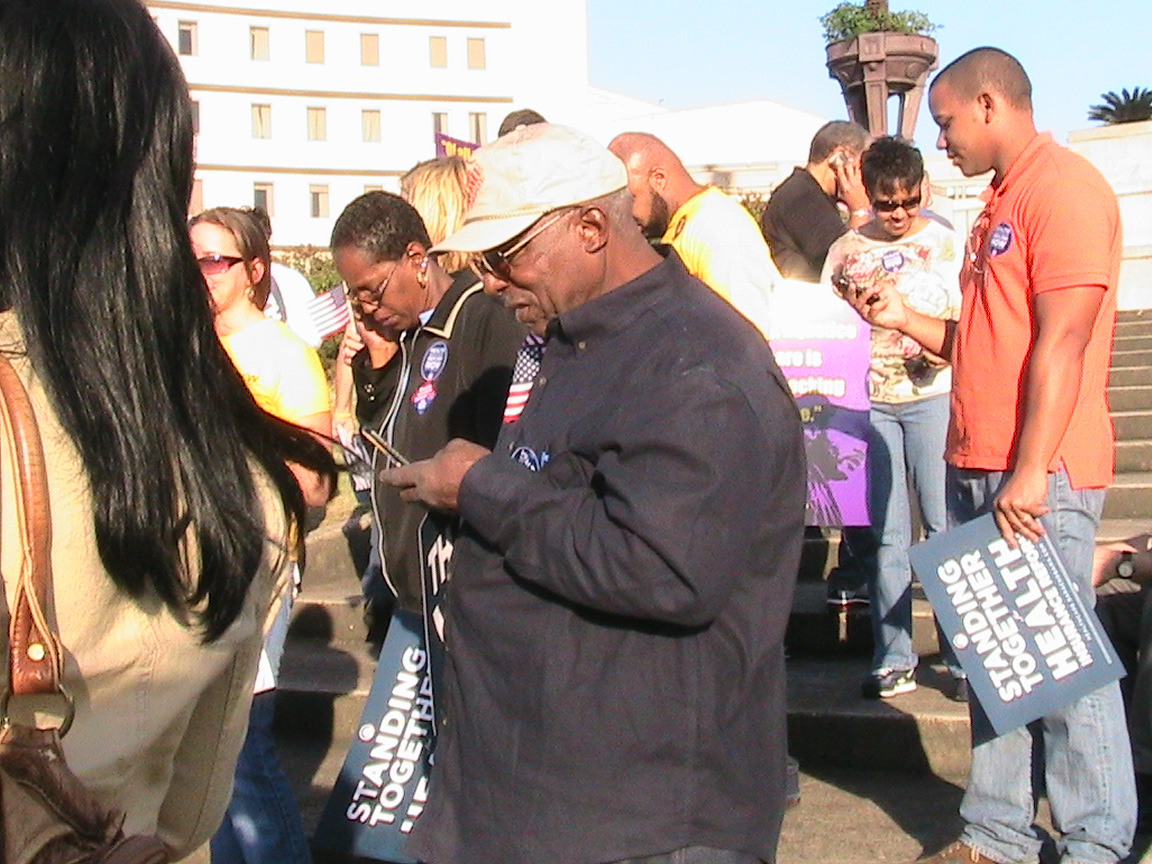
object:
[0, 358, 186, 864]
bag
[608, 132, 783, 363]
man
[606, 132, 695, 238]
head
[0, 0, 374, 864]
person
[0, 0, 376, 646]
hair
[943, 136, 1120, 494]
shirt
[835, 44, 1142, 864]
man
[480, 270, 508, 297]
nose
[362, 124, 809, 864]
person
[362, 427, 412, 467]
cell phone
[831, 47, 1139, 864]
man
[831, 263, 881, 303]
cell phone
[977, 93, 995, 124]
ear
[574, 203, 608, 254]
ear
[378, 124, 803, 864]
man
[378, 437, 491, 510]
hand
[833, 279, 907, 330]
hand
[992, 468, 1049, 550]
hand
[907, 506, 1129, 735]
sign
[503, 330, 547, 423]
flag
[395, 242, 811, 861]
shirt